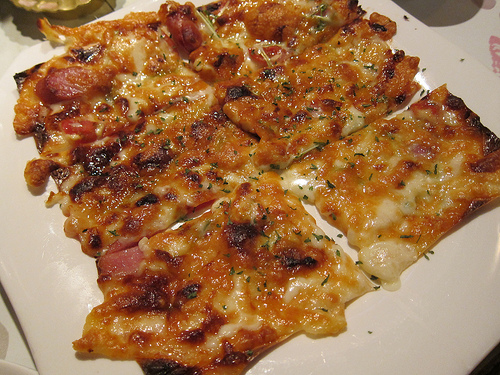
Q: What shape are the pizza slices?
A: Rectangle.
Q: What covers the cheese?
A: Herbs.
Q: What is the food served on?
A: White plate.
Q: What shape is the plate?
A: Rectangle.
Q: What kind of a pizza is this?
A: Thin crust.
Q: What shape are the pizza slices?
A: Rectangle.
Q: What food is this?
A: Pizza.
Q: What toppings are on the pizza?
A: Ham, cheese, parsley.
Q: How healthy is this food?
A: Unhealthy.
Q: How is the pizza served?
A: Sliced.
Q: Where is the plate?
A: On a table.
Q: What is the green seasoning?
A: Parsley.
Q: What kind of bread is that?
A: Cheesy bread.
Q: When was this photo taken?
A: Last week.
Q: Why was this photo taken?
A: For a magazine.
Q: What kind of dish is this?
A: An Italian dish.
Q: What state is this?
A: Illinois.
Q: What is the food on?
A: Plate.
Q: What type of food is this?
A: Pizza.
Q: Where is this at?
A: Restaurant.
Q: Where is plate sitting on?
A: Table.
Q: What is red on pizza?
A: Sauce.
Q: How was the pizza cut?
A: In squares.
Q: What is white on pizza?
A: Cheese.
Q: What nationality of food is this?
A: Italian.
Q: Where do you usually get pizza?
A: Pizza house.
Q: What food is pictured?
A: Pizza.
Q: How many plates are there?
A: One.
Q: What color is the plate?
A: White.